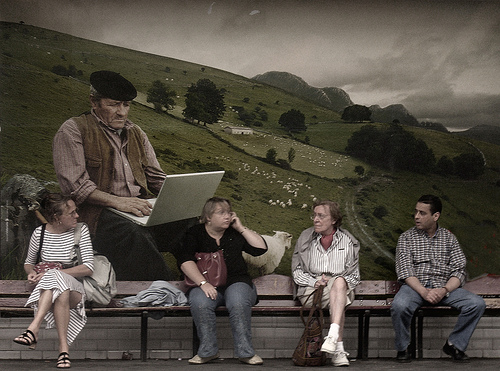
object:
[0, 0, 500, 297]
wall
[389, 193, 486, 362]
people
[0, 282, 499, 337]
bench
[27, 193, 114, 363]
woman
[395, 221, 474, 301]
shirt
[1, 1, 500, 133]
sky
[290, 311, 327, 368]
bag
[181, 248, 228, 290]
bag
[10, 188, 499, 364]
four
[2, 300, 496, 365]
bench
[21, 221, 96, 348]
dress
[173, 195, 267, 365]
woman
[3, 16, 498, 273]
grass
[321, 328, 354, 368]
shoes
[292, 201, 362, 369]
women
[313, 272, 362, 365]
crossed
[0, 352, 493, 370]
ground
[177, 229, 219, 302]
arm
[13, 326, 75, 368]
heels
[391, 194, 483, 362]
man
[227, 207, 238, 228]
cell phone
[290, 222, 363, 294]
gray jacket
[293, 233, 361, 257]
shoulders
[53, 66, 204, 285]
man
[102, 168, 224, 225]
computer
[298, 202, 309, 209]
sheep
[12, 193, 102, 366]
lady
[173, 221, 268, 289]
black shirt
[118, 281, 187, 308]
clothing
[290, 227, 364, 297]
striped shirt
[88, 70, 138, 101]
black beret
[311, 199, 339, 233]
left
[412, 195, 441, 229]
left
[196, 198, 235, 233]
right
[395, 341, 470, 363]
black shoes